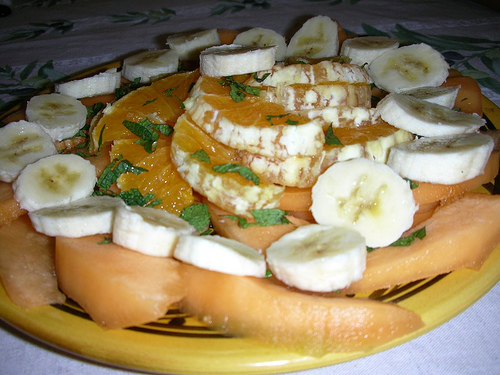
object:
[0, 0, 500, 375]
table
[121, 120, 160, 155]
chives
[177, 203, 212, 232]
herbs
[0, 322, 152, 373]
shadow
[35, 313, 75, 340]
yellow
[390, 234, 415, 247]
herb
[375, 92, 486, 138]
banana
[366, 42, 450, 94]
banana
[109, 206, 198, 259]
banana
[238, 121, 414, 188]
orange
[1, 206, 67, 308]
melon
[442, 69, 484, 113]
melon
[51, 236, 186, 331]
fruit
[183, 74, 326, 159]
fruit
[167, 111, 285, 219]
fruit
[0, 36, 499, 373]
plate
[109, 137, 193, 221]
fruit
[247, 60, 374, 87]
fruit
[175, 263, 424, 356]
melon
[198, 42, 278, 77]
banana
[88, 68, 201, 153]
oranges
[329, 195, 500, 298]
cantaloupe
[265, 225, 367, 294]
banana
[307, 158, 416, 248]
banana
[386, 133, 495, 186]
banana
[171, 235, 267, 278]
banana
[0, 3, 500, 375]
table cloth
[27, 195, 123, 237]
banana slice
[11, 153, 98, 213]
banana slice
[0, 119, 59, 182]
banana slice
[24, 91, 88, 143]
banana slice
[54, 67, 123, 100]
banana slice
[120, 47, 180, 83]
banana slice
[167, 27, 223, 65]
banana slice